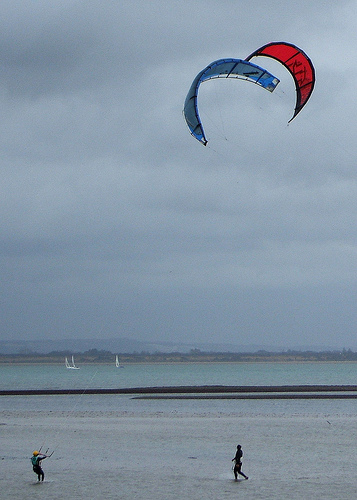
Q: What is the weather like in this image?
A: It is cloudy.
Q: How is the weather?
A: It is cloudy.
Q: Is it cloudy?
A: Yes, it is cloudy.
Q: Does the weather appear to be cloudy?
A: Yes, it is cloudy.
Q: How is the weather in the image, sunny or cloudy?
A: It is cloudy.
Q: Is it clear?
A: No, it is cloudy.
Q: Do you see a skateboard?
A: No, there are no skateboards.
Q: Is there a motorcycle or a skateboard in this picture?
A: No, there are no skateboards or motorcycles.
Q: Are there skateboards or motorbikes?
A: No, there are no skateboards or motorbikes.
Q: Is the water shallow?
A: Yes, the water is shallow.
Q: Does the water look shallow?
A: Yes, the water is shallow.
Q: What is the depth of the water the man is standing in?
A: The water is shallow.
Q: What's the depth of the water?
A: The water is shallow.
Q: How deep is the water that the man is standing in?
A: The water is shallow.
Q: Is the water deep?
A: No, the water is shallow.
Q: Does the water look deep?
A: No, the water is shallow.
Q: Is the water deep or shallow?
A: The water is shallow.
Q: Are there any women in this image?
A: No, there are no women.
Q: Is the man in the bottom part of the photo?
A: Yes, the man is in the bottom of the image.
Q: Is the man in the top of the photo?
A: No, the man is in the bottom of the image.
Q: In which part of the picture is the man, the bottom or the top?
A: The man is in the bottom of the image.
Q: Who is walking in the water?
A: The man is walking in the water.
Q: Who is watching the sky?
A: The man is watching the sky.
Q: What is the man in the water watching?
A: The man is watching the sky.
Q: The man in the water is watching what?
A: The man is watching the sky.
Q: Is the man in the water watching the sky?
A: Yes, the man is watching the sky.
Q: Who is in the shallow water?
A: The man is in the water.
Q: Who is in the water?
A: The man is in the water.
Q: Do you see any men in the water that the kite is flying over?
A: Yes, there is a man in the water.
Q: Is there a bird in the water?
A: No, there is a man in the water.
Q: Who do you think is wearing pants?
A: The man is wearing pants.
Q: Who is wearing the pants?
A: The man is wearing pants.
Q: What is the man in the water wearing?
A: The man is wearing pants.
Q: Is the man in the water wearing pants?
A: Yes, the man is wearing pants.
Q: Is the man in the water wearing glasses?
A: No, the man is wearing pants.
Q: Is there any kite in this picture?
A: Yes, there is a kite.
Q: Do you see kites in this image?
A: Yes, there is a kite.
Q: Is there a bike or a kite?
A: Yes, there is a kite.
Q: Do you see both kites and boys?
A: No, there is a kite but no boys.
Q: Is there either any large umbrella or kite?
A: Yes, there is a large kite.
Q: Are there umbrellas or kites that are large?
A: Yes, the kite is large.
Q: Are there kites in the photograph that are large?
A: Yes, there is a large kite.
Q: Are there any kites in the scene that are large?
A: Yes, there is a kite that is large.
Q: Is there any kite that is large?
A: Yes, there is a kite that is large.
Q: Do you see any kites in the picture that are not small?
A: Yes, there is a large kite.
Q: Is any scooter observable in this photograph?
A: No, there are no scooters.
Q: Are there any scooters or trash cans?
A: No, there are no scooters or trash cans.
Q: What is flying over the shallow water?
A: The kite is flying over the water.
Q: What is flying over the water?
A: The kite is flying over the water.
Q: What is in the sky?
A: The kite is in the sky.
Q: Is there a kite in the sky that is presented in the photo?
A: Yes, there is a kite in the sky.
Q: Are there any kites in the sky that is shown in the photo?
A: Yes, there is a kite in the sky.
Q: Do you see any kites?
A: Yes, there is a kite.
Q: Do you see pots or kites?
A: Yes, there is a kite.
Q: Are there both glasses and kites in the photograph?
A: No, there is a kite but no glasses.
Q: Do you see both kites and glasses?
A: No, there is a kite but no glasses.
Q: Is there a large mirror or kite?
A: Yes, there is a large kite.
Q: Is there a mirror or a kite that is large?
A: Yes, the kite is large.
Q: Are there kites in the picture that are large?
A: Yes, there is a large kite.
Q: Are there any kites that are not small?
A: Yes, there is a large kite.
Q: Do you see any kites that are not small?
A: Yes, there is a large kite.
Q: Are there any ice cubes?
A: No, there are no ice cubes.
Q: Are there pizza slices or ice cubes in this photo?
A: No, there are no ice cubes or pizza slices.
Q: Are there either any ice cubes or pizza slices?
A: No, there are no ice cubes or pizza slices.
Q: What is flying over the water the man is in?
A: The kite is flying over the water.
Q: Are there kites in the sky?
A: Yes, there is a kite in the sky.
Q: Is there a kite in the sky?
A: Yes, there is a kite in the sky.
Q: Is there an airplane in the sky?
A: No, there is a kite in the sky.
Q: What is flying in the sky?
A: The kite is flying in the sky.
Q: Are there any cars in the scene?
A: No, there are no cars.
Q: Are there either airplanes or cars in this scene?
A: No, there are no cars or airplanes.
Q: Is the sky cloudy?
A: Yes, the sky is cloudy.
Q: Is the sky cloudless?
A: No, the sky is cloudy.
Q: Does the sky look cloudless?
A: No, the sky is cloudy.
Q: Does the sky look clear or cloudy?
A: The sky is cloudy.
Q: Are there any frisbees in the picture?
A: No, there are no frisbees.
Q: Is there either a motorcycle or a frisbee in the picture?
A: No, there are no frisbees or motorcycles.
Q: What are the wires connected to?
A: The wires are connected to the kite.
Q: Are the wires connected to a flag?
A: No, the wires are connected to the kite.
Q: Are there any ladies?
A: No, there are no ladies.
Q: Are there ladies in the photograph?
A: No, there are no ladies.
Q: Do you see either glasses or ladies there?
A: No, there are no ladies or glasses.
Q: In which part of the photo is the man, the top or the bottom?
A: The man is in the bottom of the image.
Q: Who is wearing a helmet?
A: The man is wearing a helmet.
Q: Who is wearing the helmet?
A: The man is wearing a helmet.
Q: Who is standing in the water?
A: The man is standing in the water.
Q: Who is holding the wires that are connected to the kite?
A: The man is holding the wires.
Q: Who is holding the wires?
A: The man is holding the wires.